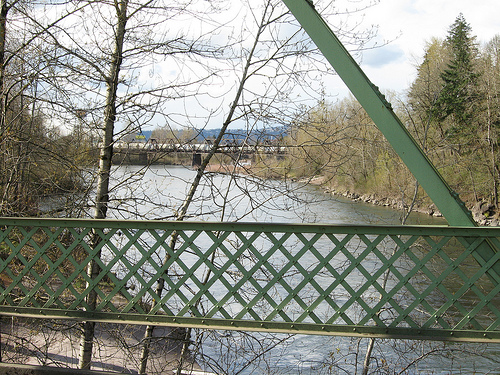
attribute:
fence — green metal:
[37, 214, 475, 344]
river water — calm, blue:
[230, 170, 379, 231]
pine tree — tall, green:
[418, 23, 486, 145]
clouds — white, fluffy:
[359, 25, 464, 80]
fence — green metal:
[7, 210, 486, 349]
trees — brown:
[7, 31, 277, 311]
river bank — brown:
[150, 309, 243, 367]